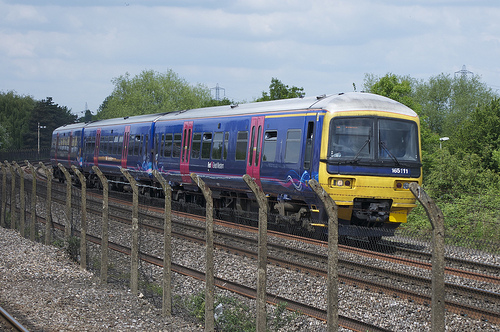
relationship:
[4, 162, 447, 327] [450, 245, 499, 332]
poles supporting fencing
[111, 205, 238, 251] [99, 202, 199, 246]
tracks on side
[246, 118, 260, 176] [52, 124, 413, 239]
doors on train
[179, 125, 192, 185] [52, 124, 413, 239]
doors on train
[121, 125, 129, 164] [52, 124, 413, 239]
doors on train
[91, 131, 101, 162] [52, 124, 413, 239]
doors on train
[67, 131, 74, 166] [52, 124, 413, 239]
doors on train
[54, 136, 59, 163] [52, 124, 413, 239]
doors on train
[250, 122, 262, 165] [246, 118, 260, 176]
windows on doors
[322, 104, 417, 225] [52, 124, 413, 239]
front of train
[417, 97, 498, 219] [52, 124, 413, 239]
trees behind train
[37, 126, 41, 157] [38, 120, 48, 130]
pole with sign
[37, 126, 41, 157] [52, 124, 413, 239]
pole behind train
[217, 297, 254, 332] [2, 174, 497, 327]
plants along fence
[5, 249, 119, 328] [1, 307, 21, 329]
gravel between rails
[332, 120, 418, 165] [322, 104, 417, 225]
windows across front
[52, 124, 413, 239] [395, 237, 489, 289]
train on tracks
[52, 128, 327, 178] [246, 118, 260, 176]
cars with doors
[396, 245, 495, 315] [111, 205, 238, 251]
sets of tracks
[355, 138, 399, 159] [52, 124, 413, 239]
wipers on train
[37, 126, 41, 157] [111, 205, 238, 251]
pole beside tracks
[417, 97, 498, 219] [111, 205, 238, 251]
trees behind tracks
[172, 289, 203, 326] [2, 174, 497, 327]
weeds along fence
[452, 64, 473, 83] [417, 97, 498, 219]
tower behind trees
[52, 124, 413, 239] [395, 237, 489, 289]
train on rails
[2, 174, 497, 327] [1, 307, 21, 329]
fence close to rails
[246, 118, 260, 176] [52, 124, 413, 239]
door of train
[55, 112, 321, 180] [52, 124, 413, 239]
side of train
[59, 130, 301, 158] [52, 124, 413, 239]
window of train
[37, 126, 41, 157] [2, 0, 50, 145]
pole in background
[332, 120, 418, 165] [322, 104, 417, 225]
window in front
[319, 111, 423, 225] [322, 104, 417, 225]
yellow in front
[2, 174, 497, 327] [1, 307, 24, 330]
fence next to rails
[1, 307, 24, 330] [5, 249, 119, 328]
rails on ground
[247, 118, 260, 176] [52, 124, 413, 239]
doors of train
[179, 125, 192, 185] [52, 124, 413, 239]
doors of train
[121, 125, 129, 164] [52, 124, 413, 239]
doors of train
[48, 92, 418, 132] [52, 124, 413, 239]
roof of train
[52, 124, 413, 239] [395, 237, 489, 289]
train going down track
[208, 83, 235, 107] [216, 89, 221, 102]
top of pole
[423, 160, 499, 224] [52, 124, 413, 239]
bushes next to train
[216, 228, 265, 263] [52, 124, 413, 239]
track next to train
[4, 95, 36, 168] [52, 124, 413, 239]
trees behind train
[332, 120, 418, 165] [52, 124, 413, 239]
windows of train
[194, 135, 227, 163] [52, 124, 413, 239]
windows of train